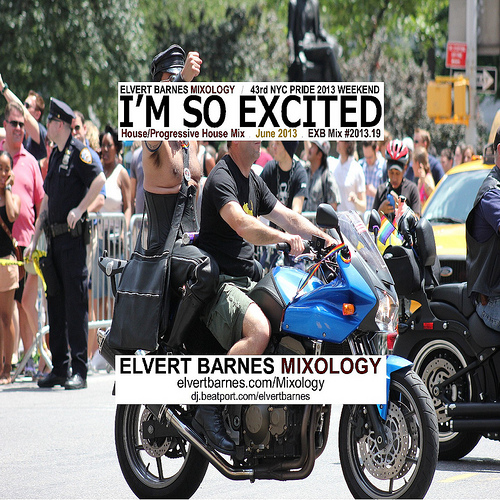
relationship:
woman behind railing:
[94, 123, 135, 215] [87, 206, 128, 223]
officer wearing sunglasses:
[38, 96, 105, 392] [47, 114, 57, 124]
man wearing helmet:
[378, 135, 426, 213] [386, 143, 409, 171]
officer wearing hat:
[38, 96, 105, 392] [49, 98, 74, 126]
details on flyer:
[124, 354, 378, 401] [112, 81, 391, 404]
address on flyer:
[187, 387, 325, 408] [112, 81, 391, 404]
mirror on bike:
[314, 202, 339, 229] [111, 207, 440, 499]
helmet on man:
[386, 143, 409, 171] [378, 135, 426, 213]